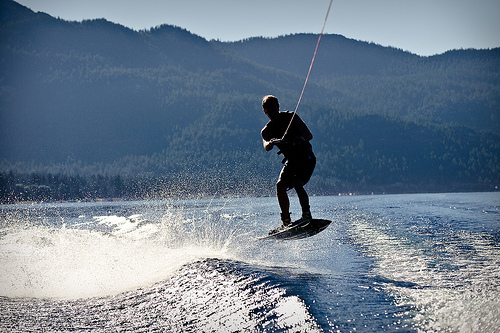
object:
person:
[253, 87, 322, 231]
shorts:
[274, 154, 322, 190]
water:
[376, 233, 498, 331]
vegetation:
[2, 158, 187, 192]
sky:
[23, 0, 500, 50]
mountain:
[70, 15, 141, 195]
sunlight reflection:
[434, 201, 493, 213]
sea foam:
[159, 252, 281, 297]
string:
[271, 4, 351, 151]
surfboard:
[261, 218, 334, 243]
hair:
[260, 91, 284, 112]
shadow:
[387, 265, 475, 294]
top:
[5, 1, 74, 28]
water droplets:
[140, 180, 258, 261]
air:
[4, 11, 499, 227]